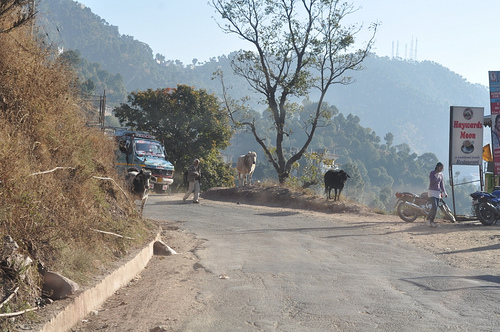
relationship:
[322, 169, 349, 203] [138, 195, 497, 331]
cow on road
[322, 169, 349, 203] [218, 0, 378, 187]
cow near tree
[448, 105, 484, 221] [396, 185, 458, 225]
sign next to motorcycle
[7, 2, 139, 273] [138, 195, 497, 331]
hillside next to road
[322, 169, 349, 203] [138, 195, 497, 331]
cow by road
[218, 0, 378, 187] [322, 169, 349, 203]
tree between cow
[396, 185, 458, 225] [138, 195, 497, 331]
motorcycle on road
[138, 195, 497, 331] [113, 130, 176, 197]
road for truck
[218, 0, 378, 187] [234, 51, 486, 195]
tree on hill